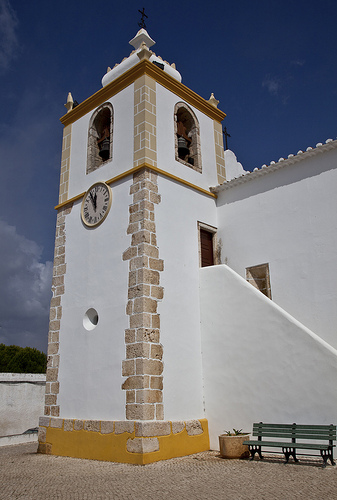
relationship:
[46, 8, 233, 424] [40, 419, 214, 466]
tower has foundation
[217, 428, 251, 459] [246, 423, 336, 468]
planter near bench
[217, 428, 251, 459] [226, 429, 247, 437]
planter has plants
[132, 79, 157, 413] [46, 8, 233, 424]
brick on tower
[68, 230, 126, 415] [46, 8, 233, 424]
stucco on tower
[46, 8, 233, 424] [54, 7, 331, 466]
tower on church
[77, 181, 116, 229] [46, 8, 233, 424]
clock on tower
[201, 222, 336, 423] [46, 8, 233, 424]
stairway leading to tower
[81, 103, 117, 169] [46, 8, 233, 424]
window on tower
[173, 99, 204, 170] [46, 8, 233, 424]
window on tower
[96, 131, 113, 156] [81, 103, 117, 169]
bell in window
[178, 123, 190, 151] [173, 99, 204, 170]
bell in window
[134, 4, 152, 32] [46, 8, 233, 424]
cross on tower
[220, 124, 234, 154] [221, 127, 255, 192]
cross on roof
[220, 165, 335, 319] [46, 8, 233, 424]
wall behind tower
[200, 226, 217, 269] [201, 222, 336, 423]
door at top of stairway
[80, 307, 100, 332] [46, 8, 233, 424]
hole in tower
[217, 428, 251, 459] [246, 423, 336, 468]
planter beside bench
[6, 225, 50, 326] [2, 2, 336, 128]
cloud in sky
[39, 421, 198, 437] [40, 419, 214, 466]
brick on foundation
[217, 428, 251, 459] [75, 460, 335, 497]
planter on ground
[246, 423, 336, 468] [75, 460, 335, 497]
bench on ground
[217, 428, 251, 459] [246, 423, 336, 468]
planter next to bench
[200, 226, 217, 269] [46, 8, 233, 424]
door on tower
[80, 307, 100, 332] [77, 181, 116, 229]
window below clock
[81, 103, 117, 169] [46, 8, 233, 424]
window at top of tower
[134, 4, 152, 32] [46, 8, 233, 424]
cross on top of tower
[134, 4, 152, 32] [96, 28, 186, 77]
cross on top of steeple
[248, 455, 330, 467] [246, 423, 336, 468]
shadow on bench